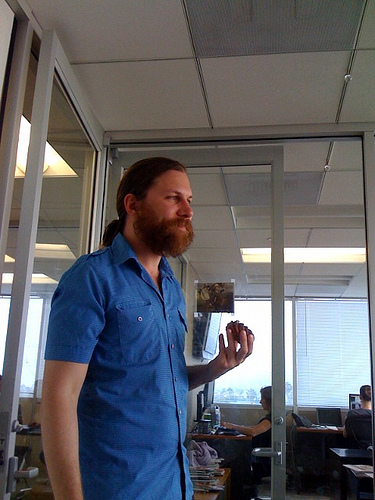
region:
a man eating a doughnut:
[35, 155, 248, 476]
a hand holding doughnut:
[210, 311, 252, 384]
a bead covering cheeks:
[140, 216, 201, 251]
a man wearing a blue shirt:
[55, 154, 209, 488]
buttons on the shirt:
[167, 338, 184, 422]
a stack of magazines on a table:
[189, 463, 221, 499]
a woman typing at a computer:
[240, 385, 274, 452]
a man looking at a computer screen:
[347, 382, 370, 437]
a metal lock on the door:
[270, 411, 288, 429]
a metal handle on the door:
[253, 438, 287, 465]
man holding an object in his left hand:
[46, 157, 273, 490]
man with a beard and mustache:
[98, 154, 210, 290]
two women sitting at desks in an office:
[201, 359, 374, 477]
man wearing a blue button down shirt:
[60, 189, 224, 494]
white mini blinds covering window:
[296, 298, 372, 411]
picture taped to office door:
[189, 272, 244, 318]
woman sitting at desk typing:
[216, 367, 282, 485]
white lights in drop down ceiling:
[179, 0, 367, 76]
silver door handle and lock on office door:
[5, 399, 46, 497]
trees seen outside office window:
[216, 382, 296, 408]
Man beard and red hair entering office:
[55, 147, 208, 278]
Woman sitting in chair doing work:
[216, 381, 291, 471]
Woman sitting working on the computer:
[319, 379, 364, 454]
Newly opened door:
[2, 230, 35, 489]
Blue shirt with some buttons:
[45, 282, 201, 494]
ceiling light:
[230, 240, 366, 263]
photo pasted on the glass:
[187, 273, 239, 314]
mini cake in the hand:
[221, 315, 268, 361]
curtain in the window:
[288, 300, 341, 398]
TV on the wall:
[192, 313, 217, 353]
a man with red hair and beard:
[43, 154, 257, 499]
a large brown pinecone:
[220, 312, 256, 351]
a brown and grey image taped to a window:
[192, 275, 239, 317]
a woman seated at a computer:
[206, 384, 280, 475]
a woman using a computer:
[335, 381, 373, 451]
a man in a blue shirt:
[37, 149, 257, 498]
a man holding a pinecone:
[31, 150, 251, 498]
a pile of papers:
[186, 439, 226, 493]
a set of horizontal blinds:
[293, 299, 369, 382]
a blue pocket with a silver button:
[113, 296, 166, 366]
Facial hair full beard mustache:
[92, 147, 203, 268]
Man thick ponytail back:
[90, 155, 150, 257]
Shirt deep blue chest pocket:
[49, 244, 181, 463]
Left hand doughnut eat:
[160, 172, 261, 399]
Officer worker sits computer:
[328, 380, 374, 460]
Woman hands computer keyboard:
[218, 380, 272, 463]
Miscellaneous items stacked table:
[179, 432, 240, 495]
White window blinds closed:
[297, 302, 374, 373]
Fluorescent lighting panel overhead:
[231, 235, 372, 273]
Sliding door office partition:
[252, 250, 298, 497]